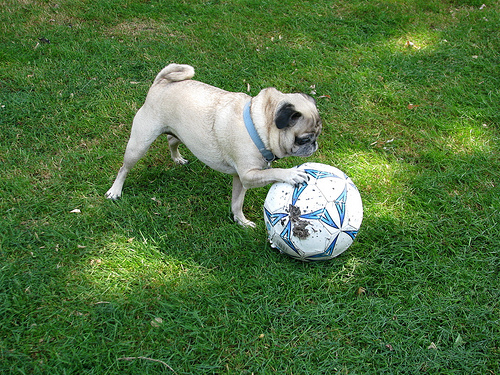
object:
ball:
[261, 160, 366, 261]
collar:
[237, 96, 280, 162]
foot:
[286, 168, 311, 187]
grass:
[353, 44, 385, 97]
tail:
[155, 62, 195, 81]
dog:
[104, 62, 320, 228]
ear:
[276, 102, 303, 129]